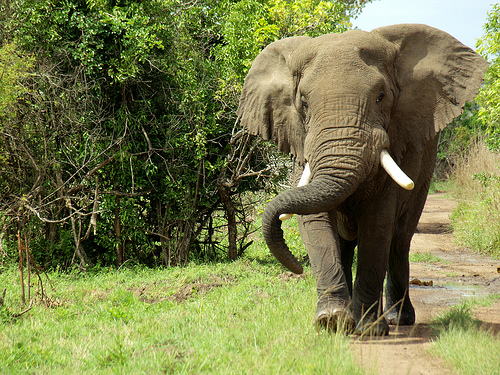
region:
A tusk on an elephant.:
[380, 148, 416, 192]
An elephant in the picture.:
[232, 23, 489, 338]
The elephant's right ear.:
[238, 32, 305, 162]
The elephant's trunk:
[262, 101, 390, 291]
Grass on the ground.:
[0, 202, 364, 374]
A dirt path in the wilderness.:
[351, 186, 493, 373]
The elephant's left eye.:
[370, 88, 392, 110]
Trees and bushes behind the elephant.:
[0, 1, 498, 274]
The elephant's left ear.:
[383, 21, 493, 152]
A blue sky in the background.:
[339, 1, 499, 63]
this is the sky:
[371, 3, 399, 21]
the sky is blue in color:
[371, 1, 401, 24]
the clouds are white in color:
[365, 0, 387, 20]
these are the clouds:
[369, 7, 388, 20]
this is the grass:
[178, 321, 230, 349]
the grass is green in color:
[203, 323, 281, 373]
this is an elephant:
[232, 14, 497, 364]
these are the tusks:
[282, 155, 417, 205]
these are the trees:
[116, 19, 211, 67]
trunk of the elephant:
[220, 140, 351, 280]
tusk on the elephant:
[367, 130, 422, 200]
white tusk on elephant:
[360, 143, 420, 201]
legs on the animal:
[273, 245, 430, 343]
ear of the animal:
[384, 28, 482, 133]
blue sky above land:
[365, 3, 428, 26]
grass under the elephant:
[197, 297, 273, 373]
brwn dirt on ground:
[372, 329, 431, 374]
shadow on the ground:
[421, 293, 488, 352]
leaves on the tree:
[89, 22, 196, 87]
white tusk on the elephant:
[372, 143, 427, 193]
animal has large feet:
[315, 314, 415, 332]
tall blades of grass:
[310, 310, 380, 365]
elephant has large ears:
[257, 40, 469, 154]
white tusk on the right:
[291, 152, 307, 197]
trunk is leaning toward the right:
[254, 163, 336, 297]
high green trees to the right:
[14, 7, 239, 257]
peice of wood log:
[413, 219, 453, 237]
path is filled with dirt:
[427, 254, 493, 320]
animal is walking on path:
[236, 37, 479, 372]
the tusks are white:
[277, 133, 429, 229]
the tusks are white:
[231, 103, 445, 258]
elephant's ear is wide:
[204, 15, 315, 195]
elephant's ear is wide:
[376, 19, 473, 184]